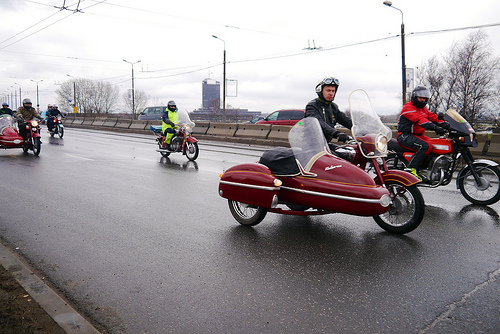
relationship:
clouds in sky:
[2, 0, 499, 116] [258, 3, 358, 52]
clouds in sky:
[2, 0, 499, 116] [8, 0, 489, 118]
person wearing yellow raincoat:
[158, 101, 191, 142] [162, 124, 164, 128]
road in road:
[409, 268, 498, 333] [2, 128, 494, 324]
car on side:
[254, 104, 306, 126] [87, 106, 498, 166]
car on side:
[138, 104, 167, 121] [87, 106, 498, 166]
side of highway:
[87, 106, 498, 166] [5, 111, 494, 324]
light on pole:
[378, 0, 409, 24] [365, 0, 442, 110]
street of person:
[4, 107, 495, 327] [2, 96, 12, 116]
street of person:
[4, 107, 495, 327] [14, 94, 44, 144]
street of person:
[4, 107, 495, 327] [161, 100, 179, 149]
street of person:
[4, 107, 495, 327] [303, 76, 352, 152]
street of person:
[4, 107, 495, 327] [398, 87, 450, 179]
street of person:
[4, 107, 495, 327] [39, 99, 59, 131]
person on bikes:
[2, 96, 12, 116] [0, 111, 41, 156]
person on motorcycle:
[14, 94, 44, 144] [13, 105, 46, 156]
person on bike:
[161, 100, 179, 149] [156, 109, 199, 161]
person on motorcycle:
[303, 76, 352, 152] [217, 90, 429, 231]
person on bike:
[398, 87, 450, 179] [371, 108, 499, 204]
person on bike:
[39, 99, 59, 131] [45, 115, 65, 137]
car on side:
[138, 104, 167, 122] [62, 106, 497, 166]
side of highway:
[62, 106, 497, 166] [5, 111, 494, 324]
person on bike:
[49, 104, 63, 133] [45, 115, 65, 140]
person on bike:
[45, 102, 52, 115] [45, 115, 65, 140]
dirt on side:
[9, 280, 58, 324] [6, 235, 137, 330]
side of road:
[6, 235, 137, 330] [2, 128, 494, 324]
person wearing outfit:
[398, 87, 450, 179] [397, 104, 443, 154]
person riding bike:
[303, 76, 348, 149] [222, 109, 428, 231]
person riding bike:
[398, 87, 452, 179] [383, 111, 499, 211]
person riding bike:
[161, 100, 179, 149] [152, 110, 201, 164]